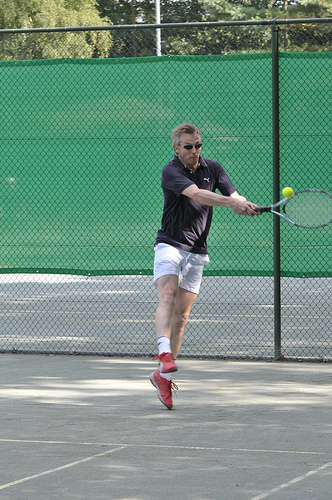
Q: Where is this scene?
A: Tennis court.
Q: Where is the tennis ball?
A: In front of the racket about to be hit.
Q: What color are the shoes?
A: Red.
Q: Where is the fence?
A: Behind the player.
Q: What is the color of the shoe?
A: Red.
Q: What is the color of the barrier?
A: Green.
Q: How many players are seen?
A: 1.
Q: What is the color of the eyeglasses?
A: Black.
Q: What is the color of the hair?
A: Brown.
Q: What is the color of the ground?
A: Grey.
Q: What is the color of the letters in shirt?
A: White.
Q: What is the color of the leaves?
A: Green.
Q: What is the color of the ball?
A: Green.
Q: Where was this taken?
A: Tennis court.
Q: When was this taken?
A: Tennis match.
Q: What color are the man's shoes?
A: Red.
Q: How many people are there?
A: 1.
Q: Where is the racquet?
A: In the man's hands.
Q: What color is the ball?
A: Yellow.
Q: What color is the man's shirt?
A: Black.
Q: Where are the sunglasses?
A: On the man's face.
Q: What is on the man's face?
A: Sunglasses.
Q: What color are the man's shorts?
A: White.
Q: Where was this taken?
A: Tennis court.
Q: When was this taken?
A: During a tennis match.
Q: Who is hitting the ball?
A: The man.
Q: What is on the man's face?
A: Sunglasses.